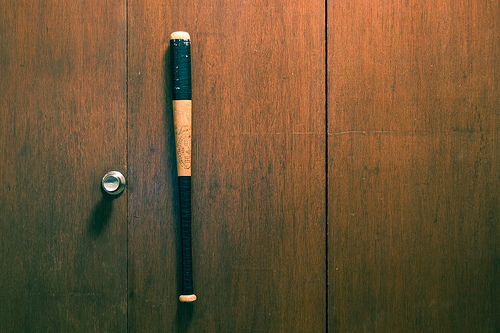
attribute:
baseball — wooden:
[168, 30, 198, 303]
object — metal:
[99, 171, 127, 194]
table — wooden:
[1, 0, 498, 328]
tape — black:
[176, 173, 196, 294]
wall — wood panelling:
[1, 0, 497, 329]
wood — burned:
[1, 0, 498, 328]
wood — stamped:
[170, 30, 197, 301]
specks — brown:
[361, 7, 386, 46]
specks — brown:
[336, 60, 388, 136]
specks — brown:
[375, 52, 435, 112]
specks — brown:
[270, 26, 325, 76]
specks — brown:
[203, 12, 267, 104]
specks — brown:
[87, 73, 119, 122]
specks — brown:
[194, 124, 266, 194]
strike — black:
[352, 259, 378, 311]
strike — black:
[70, 116, 108, 169]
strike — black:
[45, 211, 89, 286]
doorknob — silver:
[95, 168, 128, 199]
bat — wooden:
[164, 27, 201, 307]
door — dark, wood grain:
[1, 2, 132, 331]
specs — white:
[170, 59, 183, 97]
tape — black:
[165, 39, 193, 99]